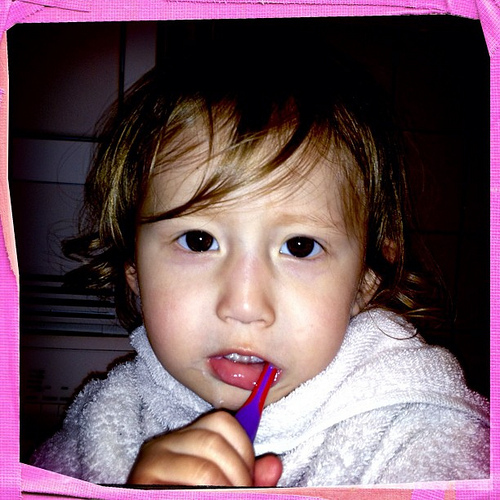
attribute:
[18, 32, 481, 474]
toddler — blond, white, staring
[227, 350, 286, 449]
toothbrush — red, purple, blue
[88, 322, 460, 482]
shirt — terrycloth, white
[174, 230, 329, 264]
eyes — brown, dark, black, almond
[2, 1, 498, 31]
border — pink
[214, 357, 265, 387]
lip — wet, pink, lower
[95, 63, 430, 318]
hair — curly, blond, brown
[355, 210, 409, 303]
ear — covered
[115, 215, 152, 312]
ear — covered